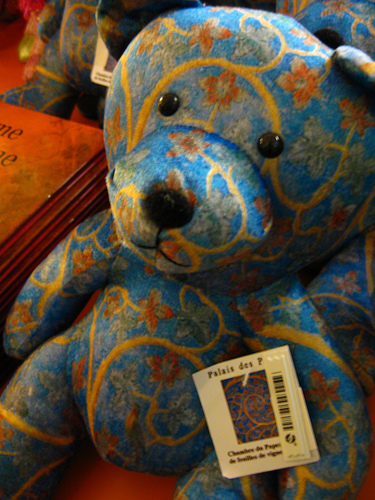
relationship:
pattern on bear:
[109, 280, 161, 361] [88, 25, 288, 459]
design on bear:
[95, 296, 203, 450] [0, 3, 375, 500]